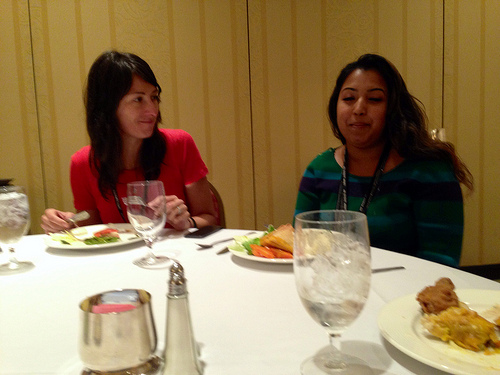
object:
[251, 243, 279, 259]
food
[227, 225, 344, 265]
plate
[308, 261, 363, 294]
ice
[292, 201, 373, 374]
glass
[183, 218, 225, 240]
phone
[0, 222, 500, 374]
table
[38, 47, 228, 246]
girl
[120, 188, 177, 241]
fork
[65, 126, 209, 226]
teeshirt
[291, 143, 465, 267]
blouse